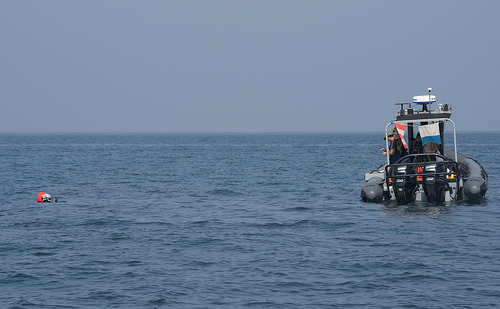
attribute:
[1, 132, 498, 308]
ocean — large, blue, water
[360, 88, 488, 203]
boat — black, gray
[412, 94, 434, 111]
antenna — white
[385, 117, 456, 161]
pole — white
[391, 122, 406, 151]
flag — orange, white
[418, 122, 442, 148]
flag — blue, white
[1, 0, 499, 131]
sky — clear, blue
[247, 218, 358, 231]
waves — small, white, green